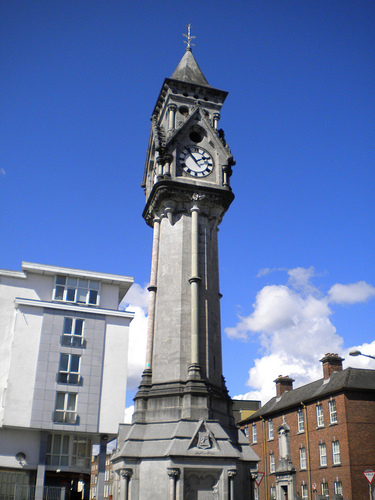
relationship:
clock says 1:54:
[163, 134, 223, 176] [184, 138, 202, 173]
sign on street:
[348, 466, 374, 491] [330, 488, 340, 489]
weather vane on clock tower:
[165, 20, 230, 60] [150, 30, 268, 387]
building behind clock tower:
[8, 271, 107, 481] [150, 30, 268, 387]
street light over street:
[338, 343, 371, 363] [330, 488, 340, 489]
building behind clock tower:
[240, 397, 361, 492] [150, 30, 268, 387]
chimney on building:
[312, 347, 358, 389] [240, 397, 361, 492]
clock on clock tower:
[163, 134, 223, 176] [150, 30, 268, 387]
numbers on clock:
[193, 142, 205, 156] [163, 134, 223, 176]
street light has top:
[338, 343, 371, 363] [348, 345, 371, 350]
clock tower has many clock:
[150, 30, 268, 387] [163, 134, 223, 176]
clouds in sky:
[225, 267, 352, 338] [268, 23, 293, 28]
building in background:
[8, 271, 107, 481] [118, 24, 128, 29]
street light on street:
[338, 343, 371, 363] [330, 488, 340, 489]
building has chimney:
[8, 271, 107, 481] [312, 347, 358, 389]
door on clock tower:
[171, 463, 228, 494] [150, 30, 268, 387]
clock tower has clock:
[150, 30, 268, 387] [163, 134, 223, 176]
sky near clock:
[268, 23, 293, 28] [163, 134, 223, 176]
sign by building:
[348, 466, 374, 491] [8, 271, 107, 481]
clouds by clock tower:
[225, 267, 352, 338] [150, 30, 268, 387]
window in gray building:
[57, 317, 106, 351] [8, 271, 107, 481]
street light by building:
[338, 343, 371, 363] [240, 397, 361, 492]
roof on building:
[271, 384, 348, 405] [240, 397, 361, 492]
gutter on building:
[254, 404, 353, 429] [240, 397, 361, 492]